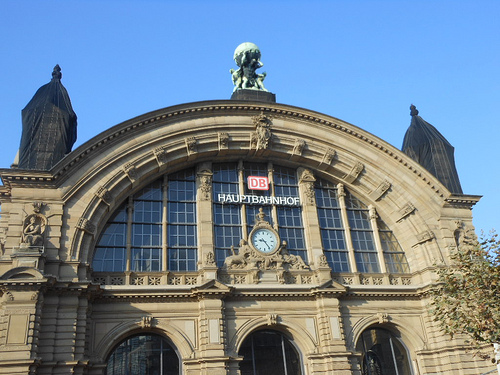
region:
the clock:
[164, 143, 330, 305]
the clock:
[211, 173, 332, 370]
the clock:
[239, 221, 296, 331]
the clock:
[208, 202, 272, 359]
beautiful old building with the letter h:
[157, 188, 350, 236]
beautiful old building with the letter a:
[194, 188, 351, 223]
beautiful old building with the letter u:
[193, 187, 325, 222]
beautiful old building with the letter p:
[197, 179, 332, 231]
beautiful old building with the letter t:
[196, 187, 319, 231]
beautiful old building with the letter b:
[189, 181, 352, 241]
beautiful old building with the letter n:
[189, 172, 329, 226]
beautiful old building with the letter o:
[199, 187, 332, 222]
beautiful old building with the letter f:
[200, 185, 318, 221]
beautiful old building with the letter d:
[229, 173, 302, 193]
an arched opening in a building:
[231, 311, 305, 374]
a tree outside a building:
[420, 225, 497, 355]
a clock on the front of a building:
[250, 222, 280, 253]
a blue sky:
[0, 1, 495, 252]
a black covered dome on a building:
[15, 60, 77, 180]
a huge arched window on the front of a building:
[65, 150, 440, 282]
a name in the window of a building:
[207, 182, 307, 204]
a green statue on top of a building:
[225, 35, 270, 91]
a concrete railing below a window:
[90, 265, 200, 290]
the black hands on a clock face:
[254, 237, 272, 251]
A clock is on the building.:
[241, 220, 290, 259]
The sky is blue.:
[285, 12, 377, 83]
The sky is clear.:
[281, 13, 397, 88]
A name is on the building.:
[206, 167, 316, 212]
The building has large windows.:
[84, 151, 413, 283]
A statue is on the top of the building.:
[199, 37, 291, 104]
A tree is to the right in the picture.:
[421, 222, 495, 369]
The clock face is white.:
[233, 207, 299, 260]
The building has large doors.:
[90, 300, 427, 372]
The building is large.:
[82, 17, 397, 372]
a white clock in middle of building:
[248, 212, 295, 252]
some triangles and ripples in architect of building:
[126, 277, 438, 304]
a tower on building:
[396, 83, 483, 206]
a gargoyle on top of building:
[201, 23, 308, 107]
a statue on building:
[2, 207, 61, 269]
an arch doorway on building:
[234, 313, 331, 372]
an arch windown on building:
[101, 10, 397, 272]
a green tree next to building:
[438, 234, 498, 355]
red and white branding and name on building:
[219, 172, 307, 217]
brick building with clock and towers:
[0, 10, 491, 372]